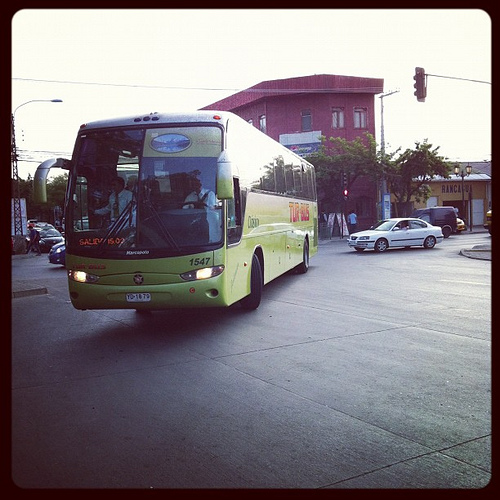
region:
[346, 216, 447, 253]
the car behind the bus is white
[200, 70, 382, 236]
the tallest building is red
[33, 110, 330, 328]
the bus is pale green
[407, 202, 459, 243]
a dark SUV is parked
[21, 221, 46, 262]
a man is walking on the sidewalk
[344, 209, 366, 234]
a man is wearing a blue shirt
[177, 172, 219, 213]
the bus driver wears a white shirt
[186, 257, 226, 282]
the bus headlight is illuminated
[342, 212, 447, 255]
the white car is following the bus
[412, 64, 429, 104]
a traffic signal hangs over the white car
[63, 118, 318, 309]
Large green bus with red lettering on the side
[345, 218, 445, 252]
White four door car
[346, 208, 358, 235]
Person in a blue shirt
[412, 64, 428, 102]
Backside of a traffic light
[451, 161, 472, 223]
Double light on a pole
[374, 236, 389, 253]
The wheel of a car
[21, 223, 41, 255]
A man walking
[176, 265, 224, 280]
Headlight that is on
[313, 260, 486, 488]
Asphalt road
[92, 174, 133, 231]
Man wearing a tie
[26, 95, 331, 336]
bus on a street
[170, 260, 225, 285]
front headlight on a vehicle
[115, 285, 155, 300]
front licence plate on a vehicle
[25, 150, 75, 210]
side rear view mirror on a vehicle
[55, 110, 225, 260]
front windshield on a vehicle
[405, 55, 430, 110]
traffic signal on a pole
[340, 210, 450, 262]
car on a street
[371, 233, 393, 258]
front wheel on a vehicle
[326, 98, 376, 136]
windows on a building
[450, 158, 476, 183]
streetlights on a pole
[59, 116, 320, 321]
green bus is turning on road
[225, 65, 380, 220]
red building is behind green bus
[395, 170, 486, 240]
small building is yellow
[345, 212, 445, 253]
white car is following green bus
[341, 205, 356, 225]
person in blue shirt is walking near red building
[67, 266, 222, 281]
green bus has yellow headlights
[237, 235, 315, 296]
green bus has black tires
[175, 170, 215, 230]
man wearing white shirt driving green bus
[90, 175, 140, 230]
man wearing tie is on green bus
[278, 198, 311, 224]
orange letters are on side of green bus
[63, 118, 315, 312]
the large green bus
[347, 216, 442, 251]
the small white car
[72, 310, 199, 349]
the shadow from the bus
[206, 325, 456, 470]
the smooth gray road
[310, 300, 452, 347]
the lines in the road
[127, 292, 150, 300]
the license plate on the bus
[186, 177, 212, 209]
the driver of the bus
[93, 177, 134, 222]
the person standing at the door of the bus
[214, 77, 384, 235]
the red building behind the bus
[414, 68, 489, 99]
the hanging traffic light